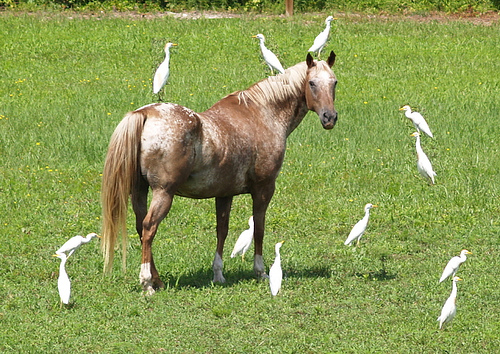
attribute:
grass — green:
[2, 0, 499, 352]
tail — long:
[98, 111, 141, 275]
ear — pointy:
[305, 52, 316, 69]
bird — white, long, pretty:
[308, 16, 335, 64]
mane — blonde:
[247, 60, 317, 108]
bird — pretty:
[268, 242, 287, 298]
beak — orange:
[252, 33, 258, 39]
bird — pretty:
[251, 30, 287, 74]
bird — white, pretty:
[150, 40, 179, 104]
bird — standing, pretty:
[412, 130, 439, 187]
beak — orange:
[171, 41, 179, 48]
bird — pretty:
[342, 202, 379, 248]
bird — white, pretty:
[440, 249, 474, 279]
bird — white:
[436, 278, 466, 329]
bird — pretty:
[60, 228, 101, 253]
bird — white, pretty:
[400, 101, 436, 137]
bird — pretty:
[232, 216, 257, 262]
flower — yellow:
[106, 108, 114, 114]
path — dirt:
[1, 4, 275, 19]